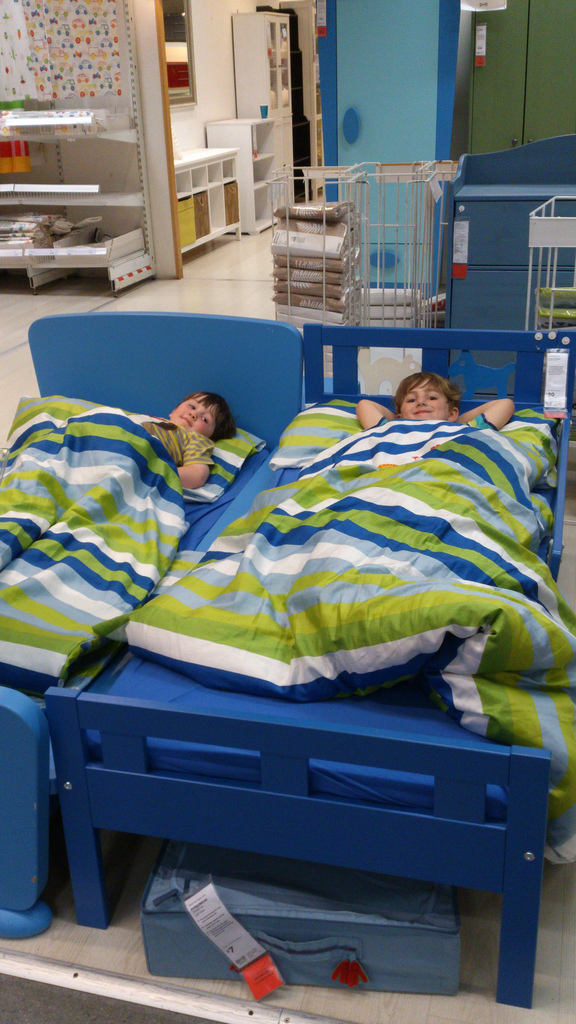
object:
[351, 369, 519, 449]
boy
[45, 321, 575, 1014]
bed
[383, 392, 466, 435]
hands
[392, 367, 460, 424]
head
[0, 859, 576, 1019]
floor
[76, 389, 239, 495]
boy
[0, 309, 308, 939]
bed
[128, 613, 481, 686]
stripe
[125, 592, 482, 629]
stripe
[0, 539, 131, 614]
stripe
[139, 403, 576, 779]
blanket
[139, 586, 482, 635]
stripe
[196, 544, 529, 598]
stripe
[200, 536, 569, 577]
stripe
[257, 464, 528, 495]
stripe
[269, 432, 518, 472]
stripe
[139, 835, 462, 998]
storage container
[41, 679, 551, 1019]
bed frame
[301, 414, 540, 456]
stripes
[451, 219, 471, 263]
label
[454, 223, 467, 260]
printing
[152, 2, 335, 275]
storage room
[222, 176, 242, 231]
shelves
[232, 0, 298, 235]
cabinets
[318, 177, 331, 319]
racks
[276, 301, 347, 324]
stacks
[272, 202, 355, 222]
linens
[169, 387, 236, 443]
head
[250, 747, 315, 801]
wood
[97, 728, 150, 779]
wood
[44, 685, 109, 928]
wood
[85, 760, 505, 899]
wood